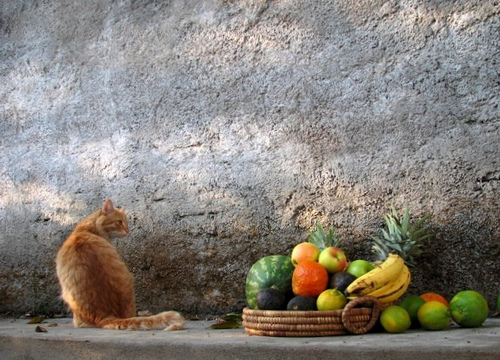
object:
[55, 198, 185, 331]
cat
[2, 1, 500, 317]
wall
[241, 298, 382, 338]
basket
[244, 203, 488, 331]
fruit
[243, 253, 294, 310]
watermellow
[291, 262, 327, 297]
orange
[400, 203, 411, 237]
leaves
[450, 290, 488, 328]
limes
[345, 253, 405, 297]
bananas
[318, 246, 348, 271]
apple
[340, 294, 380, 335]
handle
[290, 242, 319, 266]
apple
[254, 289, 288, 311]
avocado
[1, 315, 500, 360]
ledge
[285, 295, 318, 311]
avocado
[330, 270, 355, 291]
avocado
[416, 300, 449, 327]
lime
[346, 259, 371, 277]
apple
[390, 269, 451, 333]
pineapple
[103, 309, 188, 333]
tail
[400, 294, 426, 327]
lime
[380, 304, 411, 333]
lime